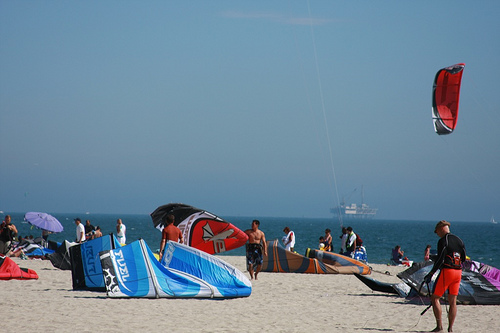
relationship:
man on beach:
[243, 219, 268, 280] [1, 256, 500, 333]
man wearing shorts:
[424, 220, 466, 332] [432, 266, 462, 299]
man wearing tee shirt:
[424, 220, 466, 332] [430, 233, 465, 275]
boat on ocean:
[489, 217, 499, 226] [3, 212, 500, 269]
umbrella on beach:
[24, 211, 64, 233] [1, 256, 500, 333]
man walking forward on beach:
[243, 219, 268, 280] [1, 256, 500, 333]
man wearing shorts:
[243, 219, 268, 280] [247, 244, 263, 265]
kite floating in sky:
[431, 62, 465, 134] [1, 1, 500, 224]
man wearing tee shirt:
[74, 217, 87, 243] [76, 223, 85, 240]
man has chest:
[243, 219, 268, 280] [249, 231, 261, 244]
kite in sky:
[431, 62, 465, 134] [1, 1, 500, 224]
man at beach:
[243, 219, 268, 280] [1, 256, 500, 333]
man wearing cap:
[424, 220, 466, 332] [435, 219, 451, 232]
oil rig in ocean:
[329, 183, 378, 221] [3, 212, 500, 269]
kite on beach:
[1, 254, 39, 280] [1, 256, 500, 333]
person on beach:
[392, 243, 407, 263] [1, 256, 500, 333]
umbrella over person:
[24, 211, 64, 233] [42, 227, 50, 242]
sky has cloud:
[1, 1, 500, 224] [221, 12, 329, 28]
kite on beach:
[99, 240, 253, 298] [1, 256, 500, 333]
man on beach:
[424, 220, 466, 332] [1, 256, 500, 333]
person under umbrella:
[42, 227, 50, 242] [24, 211, 64, 233]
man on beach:
[74, 217, 87, 243] [1, 256, 500, 333]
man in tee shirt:
[74, 217, 87, 243] [76, 223, 85, 240]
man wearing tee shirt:
[158, 214, 185, 256] [163, 224, 182, 243]